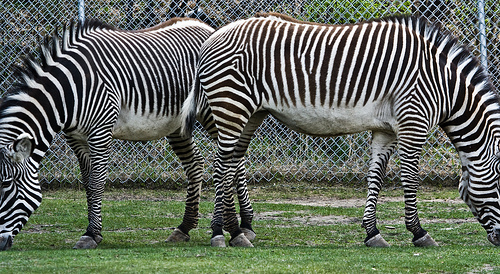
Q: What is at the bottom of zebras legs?
A: Hooves.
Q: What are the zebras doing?
A: Eating grass.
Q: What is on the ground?
A: Grass.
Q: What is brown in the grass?
A: Dirt.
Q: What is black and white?
A: Zebras.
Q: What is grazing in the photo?
A: Zebras.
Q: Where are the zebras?
A: Zoo.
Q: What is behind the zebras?
A: Fence.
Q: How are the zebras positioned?
A: Butt to butt.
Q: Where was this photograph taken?
A: In a zoo.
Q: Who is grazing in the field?
A: Zebras.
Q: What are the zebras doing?
A: Grazing.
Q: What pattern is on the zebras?
A: Striped.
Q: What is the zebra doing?
A: Eating.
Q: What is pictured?
A: The two zebras.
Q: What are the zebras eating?
A: Grass.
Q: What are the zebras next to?
A: A chain link fence.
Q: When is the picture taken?
A: During the day.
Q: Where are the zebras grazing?
A: Outside on the grass.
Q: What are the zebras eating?
A: Grass.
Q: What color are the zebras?
A: Black and white.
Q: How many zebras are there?
A: Two.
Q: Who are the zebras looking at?
A: The grass.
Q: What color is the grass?
A: Green.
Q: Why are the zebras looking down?
A: To eat the grass.